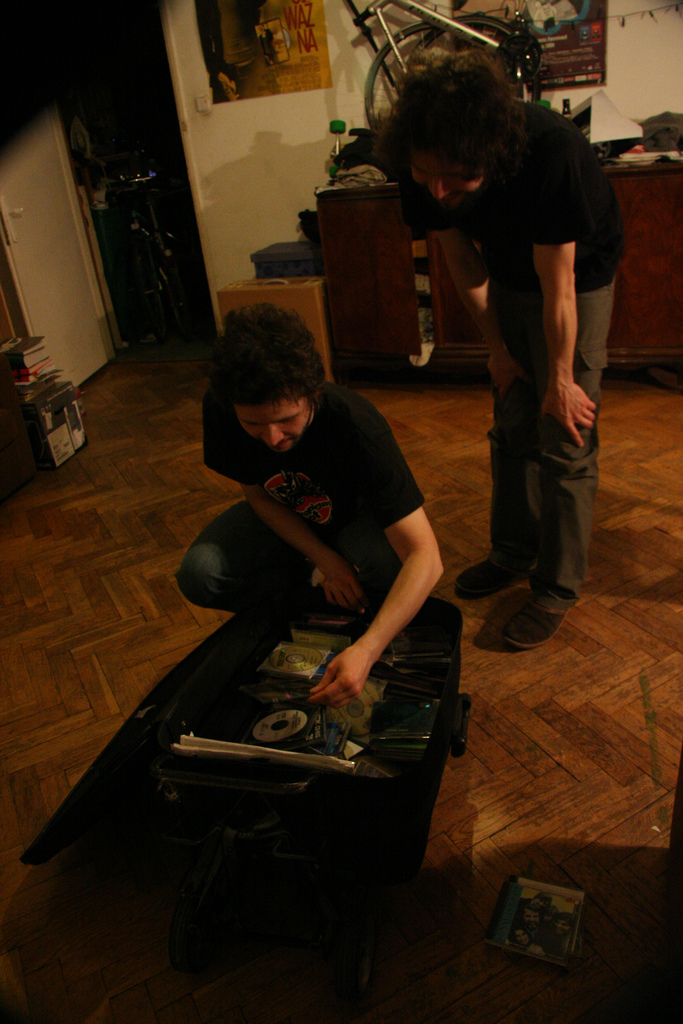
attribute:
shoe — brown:
[461, 565, 558, 655]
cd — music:
[463, 854, 601, 988]